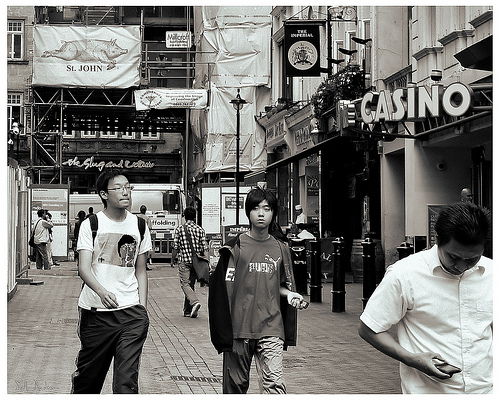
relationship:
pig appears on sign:
[41, 37, 128, 66] [32, 21, 142, 91]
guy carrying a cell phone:
[357, 201, 497, 394] [433, 360, 462, 378]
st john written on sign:
[66, 62, 104, 72] [32, 21, 142, 91]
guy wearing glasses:
[71, 168, 152, 394] [102, 183, 135, 192]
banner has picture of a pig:
[30, 21, 143, 90] [41, 37, 128, 66]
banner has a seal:
[282, 17, 322, 79] [286, 40, 318, 70]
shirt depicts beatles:
[76, 210, 150, 313] [98, 232, 139, 268]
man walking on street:
[170, 205, 210, 321] [10, 252, 400, 395]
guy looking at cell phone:
[357, 201, 497, 394] [433, 360, 462, 378]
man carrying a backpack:
[170, 205, 210, 321] [183, 223, 212, 285]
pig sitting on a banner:
[41, 37, 128, 66] [30, 21, 143, 90]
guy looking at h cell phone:
[357, 201, 497, 394] [433, 360, 462, 378]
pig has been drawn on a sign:
[41, 37, 128, 66] [32, 21, 142, 91]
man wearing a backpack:
[170, 205, 210, 321] [183, 223, 212, 285]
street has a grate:
[10, 252, 400, 395] [170, 372, 220, 386]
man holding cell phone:
[206, 186, 309, 395] [290, 295, 310, 311]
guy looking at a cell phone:
[357, 201, 497, 394] [433, 360, 462, 378]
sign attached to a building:
[331, 79, 474, 133] [367, 8, 493, 280]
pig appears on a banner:
[41, 37, 128, 66] [30, 21, 143, 90]